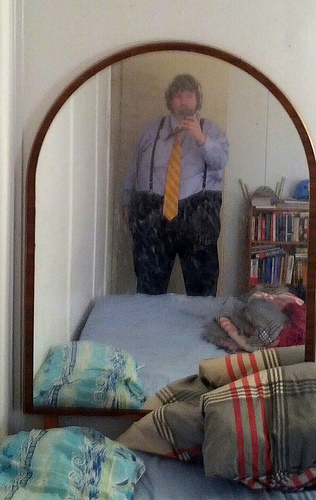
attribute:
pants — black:
[118, 176, 242, 308]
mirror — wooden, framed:
[22, 42, 315, 413]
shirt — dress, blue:
[129, 112, 237, 207]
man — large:
[114, 71, 229, 306]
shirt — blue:
[138, 117, 228, 206]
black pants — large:
[129, 189, 222, 295]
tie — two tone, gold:
[166, 126, 186, 210]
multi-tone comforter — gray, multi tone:
[199, 354, 315, 490]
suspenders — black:
[148, 115, 208, 197]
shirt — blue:
[120, 111, 229, 210]